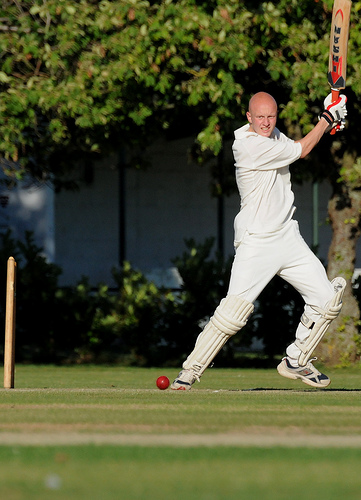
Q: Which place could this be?
A: It is a field.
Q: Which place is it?
A: It is a field.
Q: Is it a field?
A: Yes, it is a field.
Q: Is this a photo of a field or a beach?
A: It is showing a field.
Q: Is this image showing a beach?
A: No, the picture is showing a field.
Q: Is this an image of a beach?
A: No, the picture is showing a field.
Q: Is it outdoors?
A: Yes, it is outdoors.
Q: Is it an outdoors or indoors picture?
A: It is outdoors.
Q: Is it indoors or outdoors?
A: It is outdoors.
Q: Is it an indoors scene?
A: No, it is outdoors.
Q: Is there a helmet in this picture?
A: No, there are no helmets.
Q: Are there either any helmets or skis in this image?
A: No, there are no helmets or skis.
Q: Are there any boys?
A: No, there are no boys.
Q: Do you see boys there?
A: No, there are no boys.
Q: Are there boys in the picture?
A: No, there are no boys.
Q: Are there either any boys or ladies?
A: No, there are no boys or ladies.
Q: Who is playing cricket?
A: The man is playing cricket.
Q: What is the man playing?
A: The man is playing cricket.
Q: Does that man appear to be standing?
A: Yes, the man is standing.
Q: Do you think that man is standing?
A: Yes, the man is standing.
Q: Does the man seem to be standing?
A: Yes, the man is standing.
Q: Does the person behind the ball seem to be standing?
A: Yes, the man is standing.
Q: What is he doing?
A: The man is standing.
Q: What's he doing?
A: The man is standing.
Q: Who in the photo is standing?
A: The man is standing.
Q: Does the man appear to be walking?
A: No, the man is standing.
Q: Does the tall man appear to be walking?
A: No, the man is standing.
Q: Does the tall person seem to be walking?
A: No, the man is standing.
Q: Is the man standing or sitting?
A: The man is standing.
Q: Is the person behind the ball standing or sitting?
A: The man is standing.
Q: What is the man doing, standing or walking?
A: The man is standing.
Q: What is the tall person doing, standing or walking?
A: The man is standing.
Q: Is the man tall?
A: Yes, the man is tall.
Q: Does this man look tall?
A: Yes, the man is tall.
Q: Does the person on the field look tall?
A: Yes, the man is tall.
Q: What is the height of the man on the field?
A: The man is tall.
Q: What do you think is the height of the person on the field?
A: The man is tall.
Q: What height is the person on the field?
A: The man is tall.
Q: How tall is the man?
A: The man is tall.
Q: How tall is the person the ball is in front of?
A: The man is tall.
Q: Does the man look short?
A: No, the man is tall.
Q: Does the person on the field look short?
A: No, the man is tall.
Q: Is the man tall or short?
A: The man is tall.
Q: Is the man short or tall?
A: The man is tall.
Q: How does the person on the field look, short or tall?
A: The man is tall.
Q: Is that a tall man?
A: Yes, that is a tall man.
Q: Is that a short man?
A: No, that is a tall man.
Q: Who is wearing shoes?
A: The man is wearing shoes.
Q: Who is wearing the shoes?
A: The man is wearing shoes.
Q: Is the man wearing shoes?
A: Yes, the man is wearing shoes.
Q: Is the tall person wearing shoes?
A: Yes, the man is wearing shoes.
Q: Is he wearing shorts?
A: No, the man is wearing shoes.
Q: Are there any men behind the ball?
A: Yes, there is a man behind the ball.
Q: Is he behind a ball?
A: Yes, the man is behind a ball.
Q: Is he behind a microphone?
A: No, the man is behind a ball.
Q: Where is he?
A: The man is on the field.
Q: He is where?
A: The man is on the field.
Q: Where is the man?
A: The man is on the field.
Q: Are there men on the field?
A: Yes, there is a man on the field.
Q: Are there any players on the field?
A: No, there is a man on the field.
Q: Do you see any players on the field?
A: No, there is a man on the field.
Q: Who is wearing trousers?
A: The man is wearing trousers.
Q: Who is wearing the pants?
A: The man is wearing trousers.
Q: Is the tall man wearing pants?
A: Yes, the man is wearing pants.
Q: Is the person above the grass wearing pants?
A: Yes, the man is wearing pants.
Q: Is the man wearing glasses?
A: No, the man is wearing pants.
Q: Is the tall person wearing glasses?
A: No, the man is wearing pants.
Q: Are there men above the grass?
A: Yes, there is a man above the grass.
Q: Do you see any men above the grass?
A: Yes, there is a man above the grass.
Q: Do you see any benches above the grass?
A: No, there is a man above the grass.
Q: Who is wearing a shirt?
A: The man is wearing a shirt.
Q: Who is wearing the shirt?
A: The man is wearing a shirt.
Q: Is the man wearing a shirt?
A: Yes, the man is wearing a shirt.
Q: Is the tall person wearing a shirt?
A: Yes, the man is wearing a shirt.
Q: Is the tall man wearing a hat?
A: No, the man is wearing a shirt.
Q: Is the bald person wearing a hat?
A: No, the man is wearing a shirt.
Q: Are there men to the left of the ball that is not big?
A: No, the man is to the right of the ball.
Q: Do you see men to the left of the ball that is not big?
A: No, the man is to the right of the ball.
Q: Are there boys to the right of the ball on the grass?
A: No, there is a man to the right of the ball.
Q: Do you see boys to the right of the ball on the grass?
A: No, there is a man to the right of the ball.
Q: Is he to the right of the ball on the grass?
A: Yes, the man is to the right of the ball.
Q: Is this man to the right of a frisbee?
A: No, the man is to the right of the ball.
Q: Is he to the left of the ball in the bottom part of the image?
A: No, the man is to the right of the ball.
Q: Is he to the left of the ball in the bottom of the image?
A: No, the man is to the right of the ball.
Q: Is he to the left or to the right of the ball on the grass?
A: The man is to the right of the ball.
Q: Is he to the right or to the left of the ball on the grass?
A: The man is to the right of the ball.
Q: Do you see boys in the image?
A: No, there are no boys.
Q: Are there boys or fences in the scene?
A: No, there are no boys or fences.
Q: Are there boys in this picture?
A: No, there are no boys.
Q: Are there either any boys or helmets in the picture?
A: No, there are no boys or helmets.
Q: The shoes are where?
A: The shoes are on the grass.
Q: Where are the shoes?
A: The shoes are on the grass.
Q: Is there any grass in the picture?
A: Yes, there is grass.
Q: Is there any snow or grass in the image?
A: Yes, there is grass.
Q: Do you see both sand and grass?
A: No, there is grass but no sand.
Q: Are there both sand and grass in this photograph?
A: No, there is grass but no sand.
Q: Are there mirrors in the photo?
A: No, there are no mirrors.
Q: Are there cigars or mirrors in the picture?
A: No, there are no mirrors or cigars.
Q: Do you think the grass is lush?
A: Yes, the grass is lush.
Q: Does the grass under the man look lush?
A: Yes, the grass is lush.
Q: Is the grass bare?
A: No, the grass is lush.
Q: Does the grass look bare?
A: No, the grass is lush.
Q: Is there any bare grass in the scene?
A: No, there is grass but it is lush.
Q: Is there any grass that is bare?
A: No, there is grass but it is lush.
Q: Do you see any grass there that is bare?
A: No, there is grass but it is lush.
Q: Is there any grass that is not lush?
A: No, there is grass but it is lush.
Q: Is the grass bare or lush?
A: The grass is lush.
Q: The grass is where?
A: The grass is on the field.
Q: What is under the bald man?
A: The grass is under the man.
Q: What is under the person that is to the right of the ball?
A: The grass is under the man.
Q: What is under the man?
A: The grass is under the man.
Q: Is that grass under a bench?
A: No, the grass is under a man.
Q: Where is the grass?
A: The grass is in the field.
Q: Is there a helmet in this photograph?
A: No, there are no helmets.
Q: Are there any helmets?
A: No, there are no helmets.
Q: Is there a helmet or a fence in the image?
A: No, there are no helmets or fences.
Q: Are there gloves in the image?
A: Yes, there are gloves.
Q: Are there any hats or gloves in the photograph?
A: Yes, there are gloves.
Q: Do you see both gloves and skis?
A: No, there are gloves but no skis.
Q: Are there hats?
A: No, there are no hats.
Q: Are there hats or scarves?
A: No, there are no hats or scarves.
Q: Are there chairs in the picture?
A: No, there are no chairs.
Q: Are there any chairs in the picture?
A: No, there are no chairs.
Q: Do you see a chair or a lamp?
A: No, there are no chairs or lamps.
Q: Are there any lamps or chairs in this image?
A: No, there are no chairs or lamps.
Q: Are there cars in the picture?
A: No, there are no cars.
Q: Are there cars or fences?
A: No, there are no cars or fences.